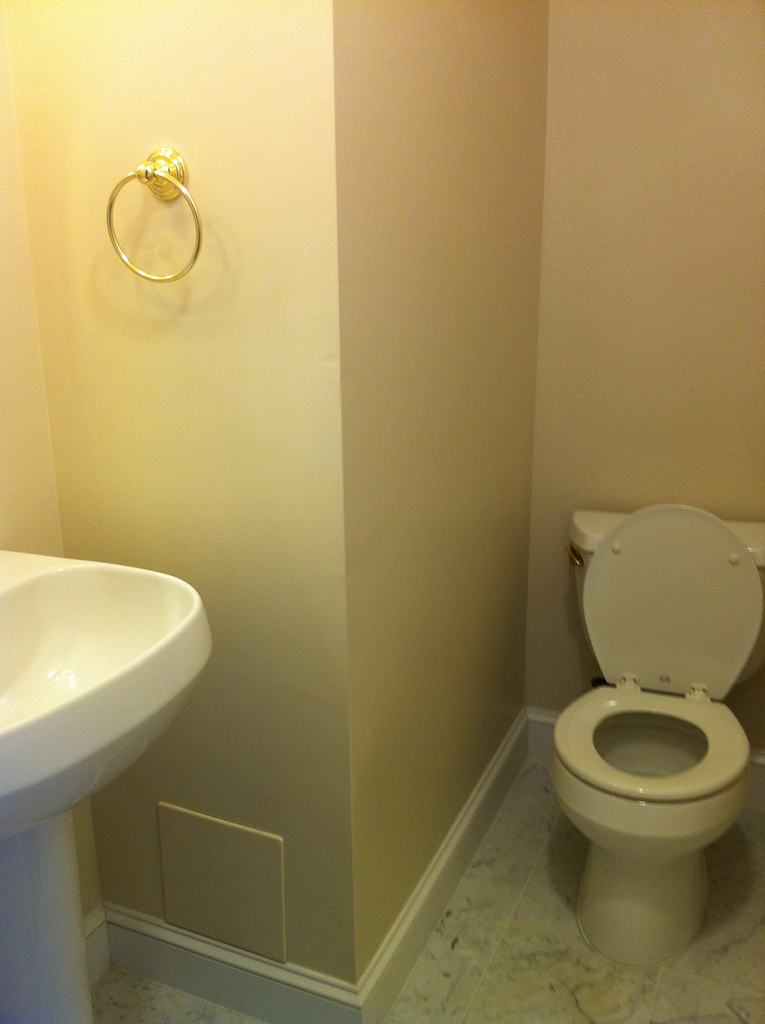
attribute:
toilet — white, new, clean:
[555, 498, 735, 983]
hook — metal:
[85, 145, 217, 295]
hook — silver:
[80, 145, 228, 284]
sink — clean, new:
[2, 512, 235, 1000]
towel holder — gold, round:
[85, 147, 210, 288]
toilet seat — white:
[557, 666, 723, 823]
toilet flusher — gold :
[555, 543, 591, 568]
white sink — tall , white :
[0, 543, 219, 1021]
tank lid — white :
[564, 506, 762, 579]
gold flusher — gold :
[559, 527, 584, 577]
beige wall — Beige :
[34, 0, 341, 1023]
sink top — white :
[9, 546, 241, 740]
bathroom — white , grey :
[17, 18, 747, 984]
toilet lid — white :
[559, 468, 762, 716]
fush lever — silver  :
[555, 546, 586, 568]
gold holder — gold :
[102, 141, 211, 303]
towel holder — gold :
[80, 122, 213, 301]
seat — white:
[529, 676, 759, 812]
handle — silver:
[559, 538, 596, 575]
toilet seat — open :
[558, 489, 762, 967]